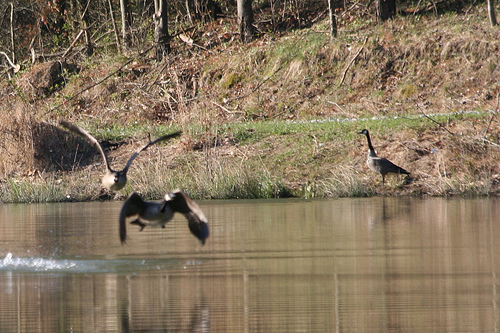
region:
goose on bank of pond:
[353, 128, 413, 186]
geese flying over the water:
[54, 121, 224, 246]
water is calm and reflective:
[282, 239, 460, 296]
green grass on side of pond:
[259, 118, 365, 135]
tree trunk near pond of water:
[148, 6, 173, 50]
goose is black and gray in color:
[357, 126, 407, 182]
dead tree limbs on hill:
[330, 35, 374, 103]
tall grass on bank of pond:
[215, 173, 295, 197]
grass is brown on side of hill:
[395, 46, 460, 98]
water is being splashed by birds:
[2, 242, 110, 278]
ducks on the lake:
[11, 14, 471, 305]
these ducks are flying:
[33, 93, 252, 272]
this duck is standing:
[339, 116, 441, 213]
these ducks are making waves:
[4, 138, 222, 301]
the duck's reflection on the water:
[73, 182, 248, 332]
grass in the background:
[12, 95, 498, 207]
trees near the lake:
[9, 7, 481, 99]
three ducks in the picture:
[43, 91, 416, 260]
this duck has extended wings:
[58, 110, 193, 180]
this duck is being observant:
[355, 128, 415, 197]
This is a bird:
[344, 118, 430, 197]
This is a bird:
[33, 112, 185, 184]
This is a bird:
[116, 184, 215, 259]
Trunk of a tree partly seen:
[69, 2, 109, 70]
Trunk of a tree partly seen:
[117, 5, 142, 42]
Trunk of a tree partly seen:
[147, 2, 179, 64]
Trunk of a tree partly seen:
[232, 4, 263, 46]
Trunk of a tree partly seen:
[324, 2, 349, 40]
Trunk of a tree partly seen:
[377, 0, 402, 25]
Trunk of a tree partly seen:
[372, 4, 400, 34]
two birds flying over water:
[70, 110, 230, 245]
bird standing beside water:
[351, 123, 416, 177]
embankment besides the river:
[7, 48, 499, 184]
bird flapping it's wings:
[57, 115, 169, 190]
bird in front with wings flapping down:
[102, 179, 214, 254]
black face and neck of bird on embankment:
[353, 125, 374, 156]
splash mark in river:
[2, 239, 93, 275]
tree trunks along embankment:
[12, 3, 498, 40]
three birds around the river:
[44, 98, 416, 239]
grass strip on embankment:
[85, 113, 455, 128]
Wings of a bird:
[172, 182, 217, 246]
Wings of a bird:
[106, 186, 153, 241]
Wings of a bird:
[41, 105, 113, 171]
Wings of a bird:
[127, 114, 184, 169]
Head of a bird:
[351, 120, 376, 145]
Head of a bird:
[155, 195, 178, 216]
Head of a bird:
[109, 165, 129, 187]